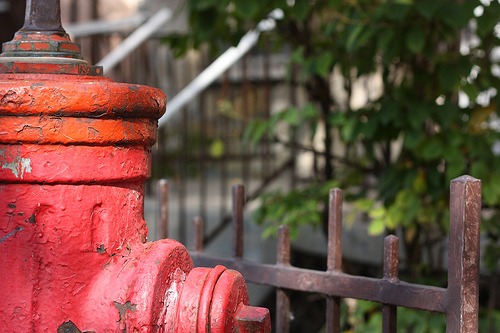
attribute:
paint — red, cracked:
[6, 23, 268, 331]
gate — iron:
[232, 186, 497, 293]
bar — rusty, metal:
[425, 166, 497, 331]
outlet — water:
[116, 241, 255, 323]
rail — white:
[155, 1, 300, 135]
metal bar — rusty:
[381, 235, 399, 331]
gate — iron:
[146, 169, 488, 330]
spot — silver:
[1, 3, 156, 100]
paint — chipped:
[105, 295, 139, 322]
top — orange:
[8, 34, 181, 151]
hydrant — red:
[0, 1, 275, 331]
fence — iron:
[156, 174, 481, 331]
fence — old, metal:
[248, 173, 488, 313]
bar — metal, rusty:
[186, 131, 497, 309]